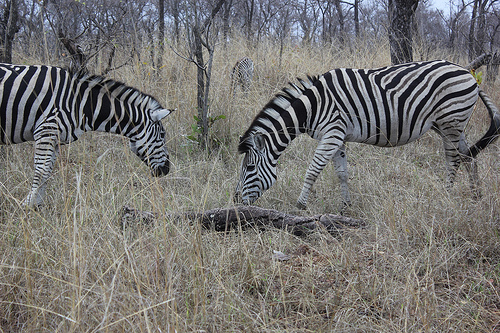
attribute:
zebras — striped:
[232, 58, 496, 209]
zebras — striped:
[3, 63, 172, 207]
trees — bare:
[288, 4, 495, 74]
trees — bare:
[8, 4, 205, 83]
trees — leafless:
[166, 3, 497, 44]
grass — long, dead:
[0, 28, 497, 331]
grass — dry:
[125, 238, 235, 323]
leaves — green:
[171, 101, 231, 161]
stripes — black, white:
[353, 73, 420, 128]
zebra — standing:
[236, 54, 498, 224]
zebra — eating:
[217, 51, 499, 208]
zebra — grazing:
[228, 61, 498, 206]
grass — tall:
[9, 59, 499, 331]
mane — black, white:
[237, 67, 326, 149]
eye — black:
[240, 154, 261, 177]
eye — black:
[139, 126, 170, 146]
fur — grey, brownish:
[61, 77, 97, 102]